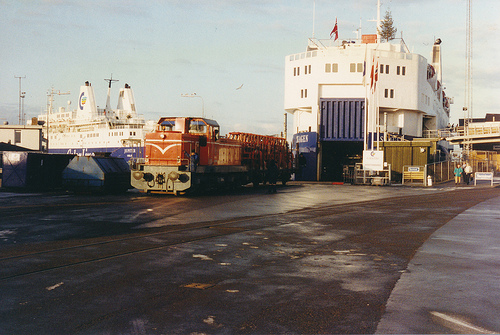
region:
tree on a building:
[365, 6, 402, 56]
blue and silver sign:
[273, 117, 321, 164]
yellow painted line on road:
[158, 255, 213, 316]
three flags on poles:
[338, 41, 388, 116]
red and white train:
[101, 115, 277, 210]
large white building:
[270, 26, 460, 143]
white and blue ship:
[31, 73, 131, 219]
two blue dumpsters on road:
[38, 145, 126, 215]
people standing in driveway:
[436, 150, 476, 202]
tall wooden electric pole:
[0, 55, 32, 127]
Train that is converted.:
[131, 118, 297, 200]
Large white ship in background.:
[31, 81, 162, 171]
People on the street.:
[453, 162, 476, 187]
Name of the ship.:
[77, 90, 92, 112]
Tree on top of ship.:
[376, 6, 402, 41]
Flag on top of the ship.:
[328, 18, 344, 49]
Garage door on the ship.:
[314, 97, 373, 187]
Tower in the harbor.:
[456, 3, 491, 185]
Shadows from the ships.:
[1, 128, 225, 229]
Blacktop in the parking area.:
[13, 187, 494, 333]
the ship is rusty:
[228, 42, 433, 245]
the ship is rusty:
[33, 83, 158, 216]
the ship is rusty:
[6, 56, 188, 268]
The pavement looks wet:
[263, 217, 430, 305]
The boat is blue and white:
[31, 42, 181, 175]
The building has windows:
[279, 50, 439, 141]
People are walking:
[451, 157, 478, 190]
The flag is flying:
[326, 9, 343, 48]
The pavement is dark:
[46, 235, 113, 295]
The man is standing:
[144, 111, 239, 177]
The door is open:
[301, 116, 412, 207]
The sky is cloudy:
[165, 31, 304, 133]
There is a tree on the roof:
[368, 8, 409, 61]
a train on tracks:
[108, 66, 320, 235]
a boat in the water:
[24, 57, 186, 174]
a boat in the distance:
[7, 42, 180, 180]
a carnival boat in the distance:
[4, 52, 214, 226]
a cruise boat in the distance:
[3, 60, 208, 227]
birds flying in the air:
[171, 35, 260, 102]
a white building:
[232, 2, 462, 195]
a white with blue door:
[278, 13, 479, 208]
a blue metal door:
[297, 84, 376, 174]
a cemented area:
[58, 161, 494, 334]